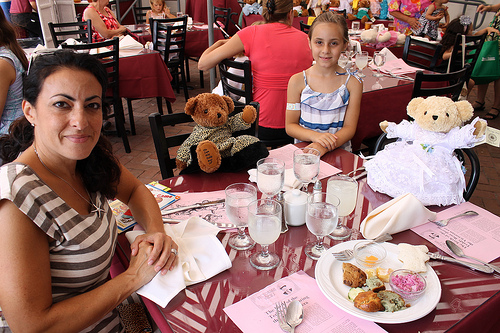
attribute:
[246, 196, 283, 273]
glasses — filled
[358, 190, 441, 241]
napkin — folded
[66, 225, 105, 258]
stripe — brown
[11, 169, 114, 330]
stripe — brown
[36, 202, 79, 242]
stripe — brown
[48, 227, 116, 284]
stripe — brown